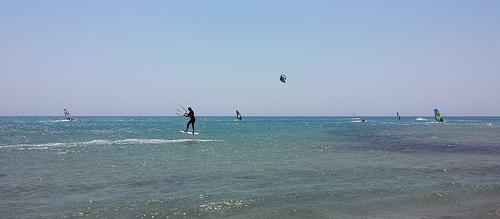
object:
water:
[0, 115, 498, 218]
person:
[360, 118, 366, 123]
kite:
[278, 74, 286, 83]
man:
[182, 107, 197, 135]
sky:
[0, 0, 499, 117]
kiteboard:
[178, 130, 199, 136]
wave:
[0, 116, 499, 218]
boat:
[62, 109, 76, 122]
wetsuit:
[184, 111, 194, 132]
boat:
[235, 110, 242, 121]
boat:
[432, 108, 444, 122]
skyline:
[1, 115, 498, 117]